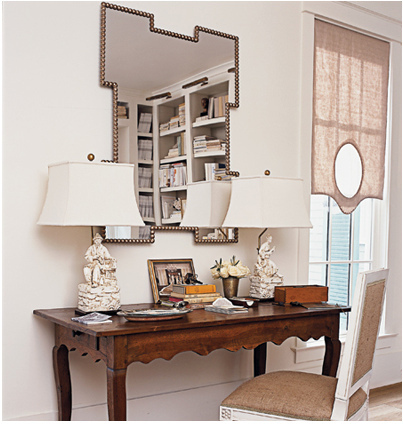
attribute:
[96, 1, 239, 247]
mirror — hanging, gold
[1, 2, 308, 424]
wall — white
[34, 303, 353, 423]
table — wood, brown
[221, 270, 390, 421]
chair — white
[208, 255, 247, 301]
vase — small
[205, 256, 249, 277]
flowers — white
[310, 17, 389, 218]
curtain — beige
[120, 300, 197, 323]
plate — antique, blue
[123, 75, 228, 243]
reflection — white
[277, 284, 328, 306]
box — wood, small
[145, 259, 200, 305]
picture — leaning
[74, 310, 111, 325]
notepad — small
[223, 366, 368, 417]
seat — burlap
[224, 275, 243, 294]
bucket — gold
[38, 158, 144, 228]
lampshade — white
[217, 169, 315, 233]
lampshade — white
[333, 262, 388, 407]
backrest — taupe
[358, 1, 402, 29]
ceiling — white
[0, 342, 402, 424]
floor boards — white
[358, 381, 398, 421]
floor — wood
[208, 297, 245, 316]
book — small